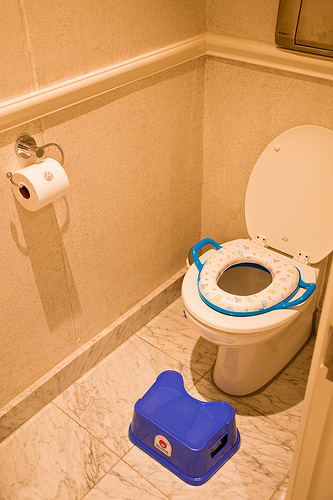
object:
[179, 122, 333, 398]
toilet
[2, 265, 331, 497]
tiles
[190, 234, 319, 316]
seat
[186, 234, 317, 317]
toddler seat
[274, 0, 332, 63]
holder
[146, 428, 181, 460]
sticker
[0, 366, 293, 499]
ground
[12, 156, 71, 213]
paper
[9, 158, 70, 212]
tissue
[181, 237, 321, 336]
seat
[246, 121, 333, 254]
seat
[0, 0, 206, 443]
wall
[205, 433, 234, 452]
handle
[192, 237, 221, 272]
seat handle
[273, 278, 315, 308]
seat handle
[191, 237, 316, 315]
potty seat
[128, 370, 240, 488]
stepstool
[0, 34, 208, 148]
molding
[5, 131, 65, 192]
dispenser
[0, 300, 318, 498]
floor